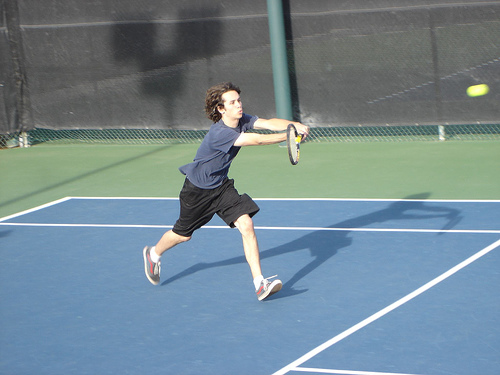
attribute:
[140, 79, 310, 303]
man — running, playing tennis, young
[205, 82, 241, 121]
hair — brown, windblown, curly, long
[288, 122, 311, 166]
tennis racket — black, white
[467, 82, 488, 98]
tennis ball — flying in air, bright yellow, yellow, green, in motion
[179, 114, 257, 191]
t-shirt — gray, blue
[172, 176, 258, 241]
shorts — black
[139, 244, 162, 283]
athletic shoe — gray, white, red, black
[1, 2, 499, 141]
net — black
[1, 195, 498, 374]
ground — blue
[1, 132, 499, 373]
tennis court — light blue, light green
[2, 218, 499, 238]
line — white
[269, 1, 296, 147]
pole — thick, green, metal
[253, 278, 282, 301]
athletic shoe — white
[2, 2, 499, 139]
fence — green